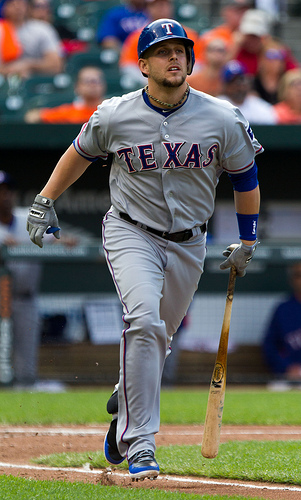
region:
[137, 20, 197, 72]
The helmet the player is wearing.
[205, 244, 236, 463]
The bat the player is holding.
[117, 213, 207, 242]
The black belt the player is wearing.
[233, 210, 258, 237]
The blue sweatband on the player's right wrist.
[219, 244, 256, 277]
The glove on the player's right wrist.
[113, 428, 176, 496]
a man wearing cleits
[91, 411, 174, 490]
a man wearing baseball cliets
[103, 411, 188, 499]
a man wearing blue cleits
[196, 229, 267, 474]
a man holding a bat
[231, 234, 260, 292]
a man wearing gray gloves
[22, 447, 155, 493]
a white line on the ground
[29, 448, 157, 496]
a white line on the dirt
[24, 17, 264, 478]
this is a man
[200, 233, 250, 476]
a wooden baseball bat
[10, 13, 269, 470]
a man holding a baseball bat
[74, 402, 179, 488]
man wearing blue shoes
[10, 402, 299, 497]
white lines on the ground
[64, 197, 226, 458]
man wearing grey pants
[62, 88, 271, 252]
man wearing a grey jersey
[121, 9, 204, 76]
a blue baseball helmet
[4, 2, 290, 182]
spectators watching baseball game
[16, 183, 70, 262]
a grey baseball glove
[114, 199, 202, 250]
batter has black belt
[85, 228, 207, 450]
batter has grey pants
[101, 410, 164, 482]
batter has blue shoes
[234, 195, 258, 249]
batter has blue wristband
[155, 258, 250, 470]
batter has brown bat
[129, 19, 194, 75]
Blue helmet on a baseball player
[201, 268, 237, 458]
A wooden bat in a man's hand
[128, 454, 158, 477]
Blue baseball shoe on man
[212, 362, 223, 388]
Black logo on a bat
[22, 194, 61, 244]
Gray glove on a man's hand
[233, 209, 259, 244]
Blue band on a man's arm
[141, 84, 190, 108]
Jewelry around a man's neck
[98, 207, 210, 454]
Light gray uniform pants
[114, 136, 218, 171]
The word TEXAS across a shirt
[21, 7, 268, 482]
baseball player holding a bat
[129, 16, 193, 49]
blue helmet of man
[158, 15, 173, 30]
letter T on helmet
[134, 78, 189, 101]
necklace around man's neck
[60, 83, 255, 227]
jersey of the man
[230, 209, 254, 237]
blue colored sweatband on arm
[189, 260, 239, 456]
wooden bat in hand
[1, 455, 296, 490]
white colored line on the ground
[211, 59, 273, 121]
man with a blue hat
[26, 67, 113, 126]
man in an orange shirt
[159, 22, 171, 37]
a T on a helmet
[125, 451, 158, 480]
blue and white shoes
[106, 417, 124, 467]
a blue and black shoe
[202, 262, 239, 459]
a large wooden bat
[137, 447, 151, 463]
a grey shoe lace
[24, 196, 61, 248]
a grey and white glove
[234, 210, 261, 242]
a blue and white arm band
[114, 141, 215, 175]
the word texas on a jersey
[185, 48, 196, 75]
a helmet ear covering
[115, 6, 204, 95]
A person is sitting down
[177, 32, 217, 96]
A person is sitting down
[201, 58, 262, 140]
A person is sitting down